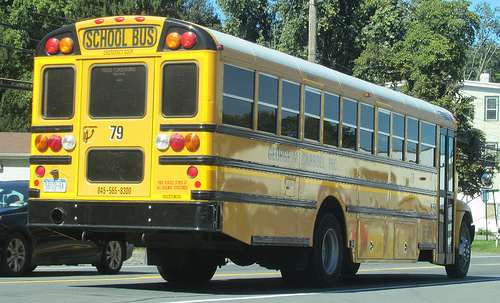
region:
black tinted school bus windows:
[35, 61, 205, 191]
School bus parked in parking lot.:
[22, 11, 479, 288]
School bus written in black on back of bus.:
[77, 23, 161, 56]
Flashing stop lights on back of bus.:
[40, 32, 202, 54]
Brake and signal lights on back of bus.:
[31, 128, 202, 154]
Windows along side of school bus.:
[234, 64, 436, 174]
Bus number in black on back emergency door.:
[103, 119, 141, 148]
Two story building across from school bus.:
[425, 36, 497, 255]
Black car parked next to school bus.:
[2, 173, 129, 281]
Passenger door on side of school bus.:
[433, 117, 460, 267]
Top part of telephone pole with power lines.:
[298, 3, 410, 79]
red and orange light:
[44, 33, 81, 58]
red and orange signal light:
[38, 38, 74, 57]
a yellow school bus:
[16, 8, 481, 291]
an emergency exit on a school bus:
[56, 46, 166, 220]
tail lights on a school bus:
[27, 126, 77, 161]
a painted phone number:
[81, 178, 145, 202]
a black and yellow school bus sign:
[73, 23, 166, 56]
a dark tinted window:
[86, 61, 151, 118]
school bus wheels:
[290, 194, 360, 291]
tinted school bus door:
[428, 118, 461, 276]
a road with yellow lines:
[6, 274, 191, 299]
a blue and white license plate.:
[34, 173, 76, 198]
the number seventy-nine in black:
[105, 119, 128, 145]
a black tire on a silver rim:
[305, 207, 361, 287]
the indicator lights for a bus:
[151, 128, 213, 159]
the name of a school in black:
[257, 139, 366, 180]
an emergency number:
[90, 182, 140, 199]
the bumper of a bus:
[17, 192, 227, 246]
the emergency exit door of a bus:
[72, 58, 166, 203]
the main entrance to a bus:
[429, 122, 461, 282]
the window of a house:
[482, 90, 499, 127]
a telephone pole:
[290, 5, 339, 51]